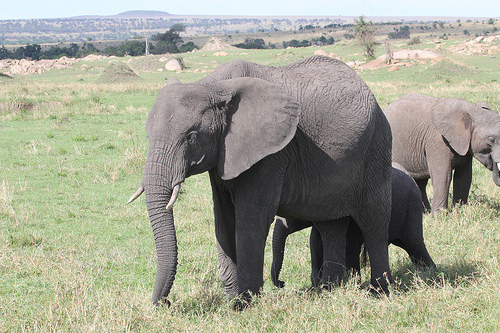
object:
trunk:
[139, 145, 179, 308]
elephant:
[126, 56, 395, 311]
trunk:
[488, 142, 498, 187]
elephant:
[379, 96, 498, 217]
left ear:
[215, 77, 301, 181]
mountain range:
[2, 8, 485, 35]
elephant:
[268, 161, 439, 290]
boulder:
[163, 57, 185, 73]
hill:
[103, 8, 181, 17]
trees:
[0, 25, 199, 60]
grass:
[0, 61, 500, 331]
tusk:
[163, 183, 181, 211]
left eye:
[183, 130, 202, 141]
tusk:
[122, 185, 146, 205]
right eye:
[289, 218, 300, 226]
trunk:
[266, 217, 286, 289]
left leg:
[226, 151, 284, 310]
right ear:
[429, 99, 472, 156]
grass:
[3, 82, 163, 123]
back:
[208, 53, 374, 130]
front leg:
[211, 179, 242, 299]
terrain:
[0, 13, 500, 78]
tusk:
[493, 160, 500, 176]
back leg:
[354, 180, 395, 297]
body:
[296, 70, 384, 189]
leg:
[424, 140, 452, 219]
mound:
[200, 35, 231, 50]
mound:
[368, 49, 444, 69]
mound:
[470, 33, 500, 50]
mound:
[1, 58, 44, 74]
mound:
[50, 54, 75, 72]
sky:
[0, 0, 497, 16]